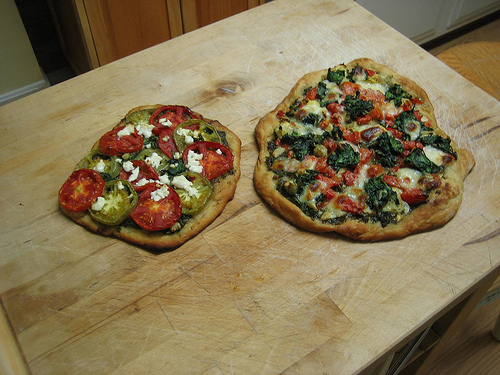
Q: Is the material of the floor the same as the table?
A: Yes, both the floor and the table are made of wood.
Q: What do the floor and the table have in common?
A: The material, both the floor and the table are wooden.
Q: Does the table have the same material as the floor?
A: Yes, both the table and the floor are made of wood.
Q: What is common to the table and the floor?
A: The material, both the table and the floor are wooden.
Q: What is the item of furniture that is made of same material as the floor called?
A: The piece of furniture is a table.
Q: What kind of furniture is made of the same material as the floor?
A: The table is made of the same material as the floor.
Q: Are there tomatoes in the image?
A: Yes, there is a tomato.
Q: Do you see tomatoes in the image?
A: Yes, there is a tomato.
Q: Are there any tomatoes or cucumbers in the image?
A: Yes, there is a tomato.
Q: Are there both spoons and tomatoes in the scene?
A: No, there is a tomato but no spoons.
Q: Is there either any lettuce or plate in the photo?
A: No, there are no lettuce or plates.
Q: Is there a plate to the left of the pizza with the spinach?
A: No, there is a tomato to the left of the pizza.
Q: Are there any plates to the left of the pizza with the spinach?
A: No, there is a tomato to the left of the pizza.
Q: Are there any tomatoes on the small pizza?
A: Yes, there is a tomato on the pizza.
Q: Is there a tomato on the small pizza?
A: Yes, there is a tomato on the pizza.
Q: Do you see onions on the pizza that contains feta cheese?
A: No, there is a tomato on the pizza.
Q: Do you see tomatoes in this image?
A: Yes, there is a tomato.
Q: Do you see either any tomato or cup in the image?
A: Yes, there is a tomato.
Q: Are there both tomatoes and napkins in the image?
A: No, there is a tomato but no napkins.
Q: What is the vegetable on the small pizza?
A: The vegetable is a tomato.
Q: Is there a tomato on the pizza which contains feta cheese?
A: Yes, there is a tomato on the pizza.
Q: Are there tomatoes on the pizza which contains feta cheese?
A: Yes, there is a tomato on the pizza.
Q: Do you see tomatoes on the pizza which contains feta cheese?
A: Yes, there is a tomato on the pizza.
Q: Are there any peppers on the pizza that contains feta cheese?
A: No, there is a tomato on the pizza.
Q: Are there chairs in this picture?
A: No, there are no chairs.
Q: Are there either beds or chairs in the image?
A: No, there are no chairs or beds.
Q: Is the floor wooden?
A: Yes, the floor is wooden.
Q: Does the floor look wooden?
A: Yes, the floor is wooden.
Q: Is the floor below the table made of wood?
A: Yes, the floor is made of wood.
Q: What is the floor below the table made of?
A: The floor is made of wood.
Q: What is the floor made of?
A: The floor is made of wood.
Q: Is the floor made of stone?
A: No, the floor is made of wood.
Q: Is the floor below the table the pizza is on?
A: Yes, the floor is below the table.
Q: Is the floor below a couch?
A: No, the floor is below the table.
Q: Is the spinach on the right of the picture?
A: Yes, the spinach is on the right of the image.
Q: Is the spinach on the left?
A: No, the spinach is on the right of the image.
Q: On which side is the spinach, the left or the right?
A: The spinach is on the right of the image.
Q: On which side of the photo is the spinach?
A: The spinach is on the right of the image.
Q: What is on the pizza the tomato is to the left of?
A: The spinach is on the pizza.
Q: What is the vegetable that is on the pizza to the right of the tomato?
A: The vegetable is spinach.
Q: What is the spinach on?
A: The spinach is on the pizza.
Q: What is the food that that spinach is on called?
A: The food is a pizza.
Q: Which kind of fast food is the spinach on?
A: The spinach is on the pizza.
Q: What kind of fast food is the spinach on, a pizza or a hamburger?
A: The spinach is on a pizza.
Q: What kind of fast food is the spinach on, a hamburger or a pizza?
A: The spinach is on a pizza.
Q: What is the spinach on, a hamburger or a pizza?
A: The spinach is on a pizza.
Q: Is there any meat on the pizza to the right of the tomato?
A: No, there is spinach on the pizza.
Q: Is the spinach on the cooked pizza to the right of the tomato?
A: Yes, the spinach is on the pizza.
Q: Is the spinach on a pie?
A: No, the spinach is on the pizza.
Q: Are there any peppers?
A: No, there are no peppers.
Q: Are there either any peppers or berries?
A: No, there are no peppers or berries.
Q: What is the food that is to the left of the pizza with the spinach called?
A: The food is feta cheese.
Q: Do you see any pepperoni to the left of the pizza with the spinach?
A: No, there is feta cheese to the left of the pizza.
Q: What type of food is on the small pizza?
A: The food is feta cheese.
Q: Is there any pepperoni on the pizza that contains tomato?
A: No, there is feta cheese on the pizza.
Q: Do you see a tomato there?
A: Yes, there is a tomato.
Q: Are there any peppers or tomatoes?
A: Yes, there is a tomato.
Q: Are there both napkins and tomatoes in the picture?
A: No, there is a tomato but no napkins.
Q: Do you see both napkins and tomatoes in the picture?
A: No, there is a tomato but no napkins.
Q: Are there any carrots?
A: No, there are no carrots.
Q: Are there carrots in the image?
A: No, there are no carrots.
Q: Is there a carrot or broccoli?
A: No, there are no carrots or broccoli.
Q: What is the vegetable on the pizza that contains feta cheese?
A: The vegetable is a tomato.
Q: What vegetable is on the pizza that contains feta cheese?
A: The vegetable is a tomato.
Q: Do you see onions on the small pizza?
A: No, there is a tomato on the pizza.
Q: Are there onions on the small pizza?
A: No, there is a tomato on the pizza.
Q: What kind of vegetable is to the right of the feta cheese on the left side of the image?
A: The vegetable is a tomato.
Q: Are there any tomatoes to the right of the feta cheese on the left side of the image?
A: Yes, there is a tomato to the right of the feta cheese.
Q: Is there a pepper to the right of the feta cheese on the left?
A: No, there is a tomato to the right of the feta cheese.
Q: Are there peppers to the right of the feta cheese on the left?
A: No, there is a tomato to the right of the feta cheese.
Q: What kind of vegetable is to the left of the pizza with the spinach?
A: The vegetable is a tomato.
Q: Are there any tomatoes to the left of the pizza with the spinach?
A: Yes, there is a tomato to the left of the pizza.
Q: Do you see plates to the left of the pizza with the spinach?
A: No, there is a tomato to the left of the pizza.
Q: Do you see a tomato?
A: Yes, there is a tomato.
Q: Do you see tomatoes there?
A: Yes, there is a tomato.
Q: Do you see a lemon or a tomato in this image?
A: Yes, there is a tomato.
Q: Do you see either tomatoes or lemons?
A: Yes, there is a tomato.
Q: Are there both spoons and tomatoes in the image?
A: No, there is a tomato but no spoons.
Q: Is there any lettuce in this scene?
A: No, there is no lettuce.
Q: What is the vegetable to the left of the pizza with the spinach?
A: The vegetable is a tomato.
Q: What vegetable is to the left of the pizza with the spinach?
A: The vegetable is a tomato.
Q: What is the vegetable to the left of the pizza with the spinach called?
A: The vegetable is a tomato.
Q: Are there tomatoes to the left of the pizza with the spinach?
A: Yes, there is a tomato to the left of the pizza.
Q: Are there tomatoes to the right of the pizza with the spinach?
A: No, the tomato is to the left of the pizza.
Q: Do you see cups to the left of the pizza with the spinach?
A: No, there is a tomato to the left of the pizza.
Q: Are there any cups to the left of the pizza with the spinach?
A: No, there is a tomato to the left of the pizza.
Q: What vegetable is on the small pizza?
A: The vegetable is a tomato.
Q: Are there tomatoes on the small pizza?
A: Yes, there is a tomato on the pizza.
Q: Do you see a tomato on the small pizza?
A: Yes, there is a tomato on the pizza.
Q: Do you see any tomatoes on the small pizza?
A: Yes, there is a tomato on the pizza.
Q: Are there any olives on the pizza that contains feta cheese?
A: No, there is a tomato on the pizza.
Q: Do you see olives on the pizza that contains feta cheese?
A: No, there is a tomato on the pizza.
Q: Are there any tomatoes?
A: Yes, there is a tomato.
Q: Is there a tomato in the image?
A: Yes, there is a tomato.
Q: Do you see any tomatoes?
A: Yes, there is a tomato.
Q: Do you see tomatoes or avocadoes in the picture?
A: Yes, there is a tomato.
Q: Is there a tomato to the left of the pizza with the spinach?
A: Yes, there is a tomato to the left of the pizza.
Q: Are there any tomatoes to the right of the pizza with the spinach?
A: No, the tomato is to the left of the pizza.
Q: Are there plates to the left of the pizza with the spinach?
A: No, there is a tomato to the left of the pizza.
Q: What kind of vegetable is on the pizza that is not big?
A: The vegetable is a tomato.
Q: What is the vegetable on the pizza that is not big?
A: The vegetable is a tomato.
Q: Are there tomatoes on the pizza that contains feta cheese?
A: Yes, there is a tomato on the pizza.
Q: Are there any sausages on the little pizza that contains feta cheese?
A: No, there is a tomato on the pizza.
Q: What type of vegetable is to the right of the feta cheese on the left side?
A: The vegetable is a tomato.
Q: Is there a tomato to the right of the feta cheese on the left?
A: Yes, there is a tomato to the right of the feta cheese.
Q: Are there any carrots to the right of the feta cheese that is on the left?
A: No, there is a tomato to the right of the feta cheese.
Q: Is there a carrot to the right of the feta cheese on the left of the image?
A: No, there is a tomato to the right of the feta cheese.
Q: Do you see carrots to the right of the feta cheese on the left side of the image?
A: No, there is a tomato to the right of the feta cheese.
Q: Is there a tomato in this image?
A: Yes, there is a tomato.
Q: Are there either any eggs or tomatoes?
A: Yes, there is a tomato.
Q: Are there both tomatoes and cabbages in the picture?
A: No, there is a tomato but no cabbages.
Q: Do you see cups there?
A: No, there are no cups.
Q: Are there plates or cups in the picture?
A: No, there are no cups or plates.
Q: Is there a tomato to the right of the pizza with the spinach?
A: No, the tomato is to the left of the pizza.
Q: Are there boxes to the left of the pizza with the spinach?
A: No, there is a tomato to the left of the pizza.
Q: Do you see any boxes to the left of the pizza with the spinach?
A: No, there is a tomato to the left of the pizza.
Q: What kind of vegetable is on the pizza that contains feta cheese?
A: The vegetable is a tomato.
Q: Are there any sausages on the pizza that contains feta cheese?
A: No, there is a tomato on the pizza.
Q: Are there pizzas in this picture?
A: Yes, there is a pizza.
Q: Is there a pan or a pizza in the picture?
A: Yes, there is a pizza.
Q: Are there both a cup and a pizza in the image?
A: No, there is a pizza but no cups.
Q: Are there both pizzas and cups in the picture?
A: No, there is a pizza but no cups.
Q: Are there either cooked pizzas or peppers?
A: Yes, there is a cooked pizza.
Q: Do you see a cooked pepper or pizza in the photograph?
A: Yes, there is a cooked pizza.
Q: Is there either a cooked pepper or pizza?
A: Yes, there is a cooked pizza.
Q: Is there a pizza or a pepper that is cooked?
A: Yes, the pizza is cooked.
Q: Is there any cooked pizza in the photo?
A: Yes, there is a cooked pizza.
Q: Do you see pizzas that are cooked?
A: Yes, there is a pizza that is cooked.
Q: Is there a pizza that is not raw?
A: Yes, there is a cooked pizza.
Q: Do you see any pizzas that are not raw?
A: Yes, there is a cooked pizza.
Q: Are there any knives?
A: No, there are no knives.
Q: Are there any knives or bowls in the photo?
A: No, there are no knives or bowls.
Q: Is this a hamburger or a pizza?
A: This is a pizza.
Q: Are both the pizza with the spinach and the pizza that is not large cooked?
A: Yes, both the pizza and the pizza are cooked.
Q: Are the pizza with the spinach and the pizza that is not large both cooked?
A: Yes, both the pizza and the pizza are cooked.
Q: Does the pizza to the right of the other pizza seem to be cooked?
A: Yes, the pizza is cooked.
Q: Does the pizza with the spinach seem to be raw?
A: No, the pizza is cooked.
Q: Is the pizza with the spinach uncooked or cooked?
A: The pizza is cooked.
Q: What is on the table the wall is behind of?
A: The pizza is on the table.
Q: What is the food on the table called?
A: The food is a pizza.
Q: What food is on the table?
A: The food is a pizza.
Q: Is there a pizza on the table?
A: Yes, there is a pizza on the table.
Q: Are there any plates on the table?
A: No, there is a pizza on the table.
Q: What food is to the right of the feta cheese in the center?
A: The food is a pizza.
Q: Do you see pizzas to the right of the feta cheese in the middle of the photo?
A: Yes, there is a pizza to the right of the feta cheese.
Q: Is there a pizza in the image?
A: Yes, there is a pizza.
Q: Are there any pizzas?
A: Yes, there is a pizza.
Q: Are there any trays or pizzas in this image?
A: Yes, there is a pizza.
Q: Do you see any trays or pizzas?
A: Yes, there is a pizza.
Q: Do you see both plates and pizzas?
A: No, there is a pizza but no plates.